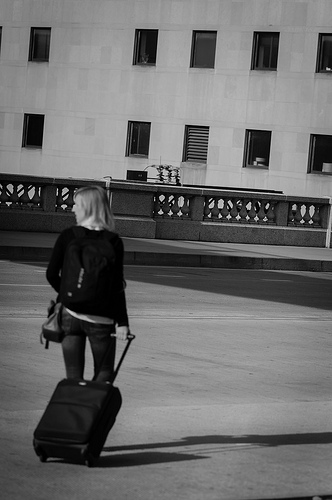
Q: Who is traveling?
A: The person pulling luggage.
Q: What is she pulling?
A: Her bag.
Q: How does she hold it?
A: By the handle.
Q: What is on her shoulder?
A: A shoulder bag.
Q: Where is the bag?
A: On her left shoulder.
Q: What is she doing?
A: Crossing the street.